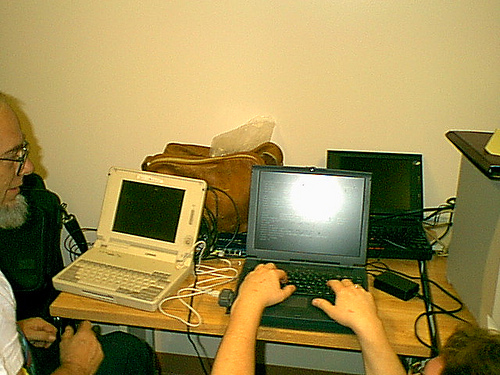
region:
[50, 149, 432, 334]
three open laptops on table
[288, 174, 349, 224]
light reflection on screen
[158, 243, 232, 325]
white wire on table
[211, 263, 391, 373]
two hands on laptop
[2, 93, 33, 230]
man with hair on chin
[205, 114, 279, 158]
top of clear plastic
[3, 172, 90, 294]
black bag with strap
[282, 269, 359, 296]
buttons on black keyboard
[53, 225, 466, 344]
surface of wood table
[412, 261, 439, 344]
space between two tables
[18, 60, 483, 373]
laptops on a desk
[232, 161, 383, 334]
this person is inputting information into this laptop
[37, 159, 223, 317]
this laptop is white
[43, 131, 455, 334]
three laptops in the photo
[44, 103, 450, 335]
these laptops are old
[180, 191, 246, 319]
a lot of cords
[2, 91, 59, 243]
the face of an older man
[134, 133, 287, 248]
a brown case behind the laptops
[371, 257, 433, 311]
a power cord for the laptop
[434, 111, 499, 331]
a container on the desk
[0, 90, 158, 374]
older adult male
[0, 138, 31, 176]
glasses to help with vision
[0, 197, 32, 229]
white hair beard indicating this is an older man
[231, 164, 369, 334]
older model of the modern day laptop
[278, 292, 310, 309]
touchpad to help with scrolling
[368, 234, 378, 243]
track ball in center of pad to help with scrolling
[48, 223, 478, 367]
brown wooden table for things to be sat on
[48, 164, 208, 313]
older white computer with no trackpad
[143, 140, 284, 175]
brown carrier bag used for carrying items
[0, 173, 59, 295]
black laptop bag for carrying laptop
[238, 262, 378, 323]
Hands on a black laptop.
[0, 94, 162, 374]
A sitting man in glasses with a grey beard.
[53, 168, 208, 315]
An old white laptop.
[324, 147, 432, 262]
Black laptop behind the rest.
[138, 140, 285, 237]
A brown bag on a table.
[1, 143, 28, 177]
Glasses on a man's face who has a beard.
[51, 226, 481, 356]
A brown table with laptops on it.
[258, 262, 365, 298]
Keyboard on a black laptop that a man is touching.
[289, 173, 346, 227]
Large white circle of glare on the computer screen.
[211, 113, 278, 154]
A clear plastic bag coming out of a brown bag.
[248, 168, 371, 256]
computer screen on lap top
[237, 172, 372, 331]
old black lap top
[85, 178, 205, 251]
computer monitor with white boarder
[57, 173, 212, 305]
white computer lap top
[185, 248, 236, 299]
white wires from laptop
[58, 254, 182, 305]
white keyboard from laptop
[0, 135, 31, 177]
black wire glasses on face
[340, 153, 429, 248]
black lap top on table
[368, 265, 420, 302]
power supply brick on table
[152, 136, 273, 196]
brown leather case on table